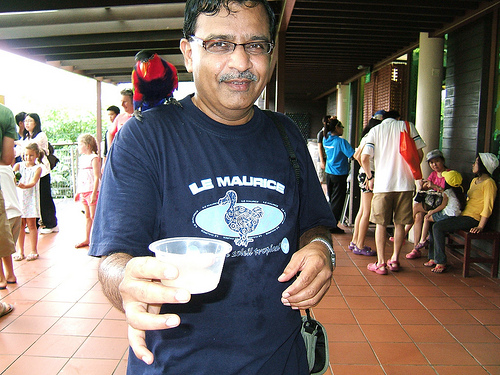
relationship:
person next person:
[70, 133, 101, 248] [11, 142, 42, 261]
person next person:
[11, 142, 42, 261] [21, 113, 58, 233]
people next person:
[359, 111, 427, 276] [106, 89, 131, 139]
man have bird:
[137, 2, 359, 373] [130, 48, 182, 124]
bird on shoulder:
[130, 48, 182, 124] [106, 103, 205, 155]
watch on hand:
[309, 235, 336, 270] [278, 237, 335, 311]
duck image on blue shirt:
[209, 184, 266, 250] [86, 93, 336, 375]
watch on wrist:
[308, 234, 338, 281] [312, 241, 334, 273]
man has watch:
[88, 0, 337, 375] [308, 234, 338, 281]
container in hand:
[148, 236, 233, 294] [113, 244, 195, 366]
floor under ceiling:
[368, 285, 474, 368] [281, 5, 496, 58]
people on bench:
[412, 136, 499, 242] [458, 230, 497, 292]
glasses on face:
[187, 35, 274, 53] [195, 0, 272, 109]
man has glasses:
[88, 0, 337, 375] [187, 35, 274, 53]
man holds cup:
[88, 0, 337, 375] [142, 235, 246, 296]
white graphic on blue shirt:
[188, 172, 293, 262] [86, 93, 336, 375]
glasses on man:
[187, 35, 275, 56] [88, 0, 337, 375]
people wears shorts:
[359, 111, 427, 276] [368, 187, 415, 228]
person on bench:
[429, 148, 498, 273] [444, 229, 500, 279]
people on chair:
[422, 153, 499, 273] [439, 227, 499, 279]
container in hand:
[148, 235, 230, 297] [116, 260, 168, 360]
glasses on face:
[187, 35, 275, 56] [196, 9, 271, 109]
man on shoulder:
[88, 0, 337, 375] [111, 106, 202, 171]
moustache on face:
[217, 70, 259, 85] [202, 13, 269, 112]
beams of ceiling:
[87, 64, 212, 82] [21, 110, 291, 181]